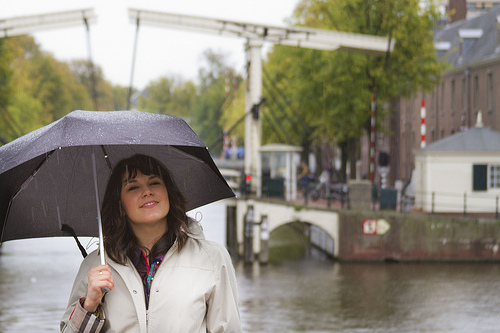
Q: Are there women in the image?
A: Yes, there is a woman.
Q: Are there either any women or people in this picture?
A: Yes, there is a woman.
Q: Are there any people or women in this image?
A: Yes, there is a woman.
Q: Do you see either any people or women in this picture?
A: Yes, there is a woman.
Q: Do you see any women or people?
A: Yes, there is a woman.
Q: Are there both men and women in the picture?
A: No, there is a woman but no men.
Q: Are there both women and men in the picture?
A: No, there is a woman but no men.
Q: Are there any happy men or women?
A: Yes, there is a happy woman.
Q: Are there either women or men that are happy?
A: Yes, the woman is happy.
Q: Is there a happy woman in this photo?
A: Yes, there is a happy woman.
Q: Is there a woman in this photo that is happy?
A: Yes, there is a happy woman.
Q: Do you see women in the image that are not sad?
A: Yes, there is a happy woman.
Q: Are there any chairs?
A: No, there are no chairs.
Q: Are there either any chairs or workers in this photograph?
A: No, there are no chairs or workers.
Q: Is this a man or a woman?
A: This is a woman.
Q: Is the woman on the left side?
A: Yes, the woman is on the left of the image.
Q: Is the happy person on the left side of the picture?
A: Yes, the woman is on the left of the image.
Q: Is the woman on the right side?
A: No, the woman is on the left of the image.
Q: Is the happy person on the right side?
A: No, the woman is on the left of the image.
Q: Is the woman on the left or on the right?
A: The woman is on the left of the image.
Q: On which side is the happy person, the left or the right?
A: The woman is on the left of the image.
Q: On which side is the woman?
A: The woman is on the left of the image.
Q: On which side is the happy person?
A: The woman is on the left of the image.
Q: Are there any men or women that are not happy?
A: No, there is a woman but she is happy.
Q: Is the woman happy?
A: Yes, the woman is happy.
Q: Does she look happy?
A: Yes, the woman is happy.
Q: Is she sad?
A: No, the woman is happy.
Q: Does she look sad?
A: No, the woman is happy.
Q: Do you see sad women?
A: No, there is a woman but she is happy.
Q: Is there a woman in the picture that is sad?
A: No, there is a woman but she is happy.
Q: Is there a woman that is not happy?
A: No, there is a woman but she is happy.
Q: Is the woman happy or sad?
A: The woman is happy.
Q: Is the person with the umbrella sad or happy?
A: The woman is happy.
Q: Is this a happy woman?
A: Yes, this is a happy woman.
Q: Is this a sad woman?
A: No, this is a happy woman.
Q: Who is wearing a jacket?
A: The woman is wearing a jacket.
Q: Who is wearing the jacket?
A: The woman is wearing a jacket.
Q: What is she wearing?
A: The woman is wearing a jacket.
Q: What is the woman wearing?
A: The woman is wearing a jacket.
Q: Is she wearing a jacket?
A: Yes, the woman is wearing a jacket.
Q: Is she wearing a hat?
A: No, the woman is wearing a jacket.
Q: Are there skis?
A: No, there are no skis.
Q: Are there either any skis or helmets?
A: No, there are no skis or helmets.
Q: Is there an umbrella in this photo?
A: Yes, there is an umbrella.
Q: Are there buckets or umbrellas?
A: Yes, there is an umbrella.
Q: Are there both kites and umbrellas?
A: No, there is an umbrella but no kites.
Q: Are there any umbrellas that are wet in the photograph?
A: Yes, there is a wet umbrella.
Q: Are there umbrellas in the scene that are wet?
A: Yes, there is an umbrella that is wet.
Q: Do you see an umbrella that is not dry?
A: Yes, there is a wet umbrella.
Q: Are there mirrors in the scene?
A: No, there are no mirrors.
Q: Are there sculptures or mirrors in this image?
A: No, there are no mirrors or sculptures.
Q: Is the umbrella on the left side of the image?
A: Yes, the umbrella is on the left of the image.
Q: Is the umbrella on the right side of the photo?
A: No, the umbrella is on the left of the image.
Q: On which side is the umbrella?
A: The umbrella is on the left of the image.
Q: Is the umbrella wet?
A: Yes, the umbrella is wet.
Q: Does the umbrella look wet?
A: Yes, the umbrella is wet.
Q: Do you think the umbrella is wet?
A: Yes, the umbrella is wet.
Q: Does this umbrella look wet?
A: Yes, the umbrella is wet.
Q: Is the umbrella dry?
A: No, the umbrella is wet.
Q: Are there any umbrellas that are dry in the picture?
A: No, there is an umbrella but it is wet.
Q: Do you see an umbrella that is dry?
A: No, there is an umbrella but it is wet.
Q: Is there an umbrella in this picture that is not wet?
A: No, there is an umbrella but it is wet.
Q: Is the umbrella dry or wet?
A: The umbrella is wet.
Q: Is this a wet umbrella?
A: Yes, this is a wet umbrella.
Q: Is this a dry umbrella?
A: No, this is a wet umbrella.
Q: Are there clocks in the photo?
A: No, there are no clocks.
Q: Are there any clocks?
A: No, there are no clocks.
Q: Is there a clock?
A: No, there are no clocks.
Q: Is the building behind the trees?
A: Yes, the building is behind the trees.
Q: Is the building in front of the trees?
A: No, the building is behind the trees.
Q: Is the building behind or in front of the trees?
A: The building is behind the trees.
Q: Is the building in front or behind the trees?
A: The building is behind the trees.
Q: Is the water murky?
A: Yes, the water is murky.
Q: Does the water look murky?
A: Yes, the water is murky.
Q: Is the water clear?
A: No, the water is murky.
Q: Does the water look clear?
A: No, the water is murky.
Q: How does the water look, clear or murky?
A: The water is murky.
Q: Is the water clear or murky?
A: The water is murky.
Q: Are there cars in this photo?
A: No, there are no cars.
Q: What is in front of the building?
A: The trees are in front of the building.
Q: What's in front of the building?
A: The trees are in front of the building.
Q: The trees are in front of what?
A: The trees are in front of the building.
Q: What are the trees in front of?
A: The trees are in front of the building.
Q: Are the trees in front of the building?
A: Yes, the trees are in front of the building.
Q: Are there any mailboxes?
A: No, there are no mailboxes.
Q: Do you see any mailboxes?
A: No, there are no mailboxes.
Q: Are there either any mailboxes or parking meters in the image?
A: No, there are no mailboxes or parking meters.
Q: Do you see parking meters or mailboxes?
A: No, there are no mailboxes or parking meters.